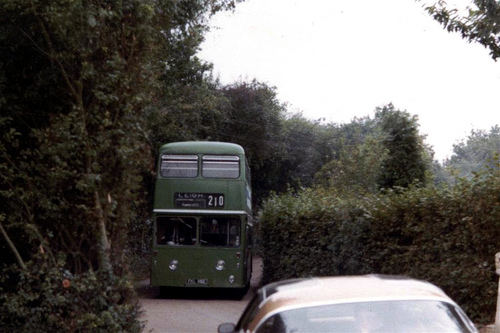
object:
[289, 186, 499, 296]
hedge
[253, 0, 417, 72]
sky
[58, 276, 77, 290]
flower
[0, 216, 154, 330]
shrub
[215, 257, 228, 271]
light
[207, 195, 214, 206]
numbers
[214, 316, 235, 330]
mirror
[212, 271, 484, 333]
car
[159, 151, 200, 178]
blind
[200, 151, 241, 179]
blind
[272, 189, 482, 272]
bush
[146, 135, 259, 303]
two fingers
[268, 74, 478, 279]
trees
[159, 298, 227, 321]
ground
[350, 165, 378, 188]
leaves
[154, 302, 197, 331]
pavement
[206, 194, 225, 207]
writing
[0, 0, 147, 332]
trees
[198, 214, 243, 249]
window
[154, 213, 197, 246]
window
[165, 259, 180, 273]
light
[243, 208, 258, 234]
mirror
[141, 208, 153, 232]
mirror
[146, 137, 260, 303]
bus